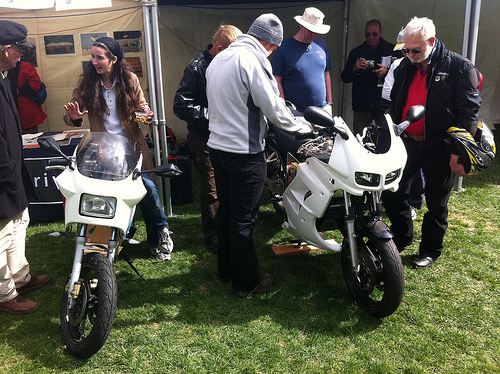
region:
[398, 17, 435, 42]
short cut white hair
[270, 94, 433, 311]
part of a white motorcycle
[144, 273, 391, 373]
a section of green grass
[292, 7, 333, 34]
a large white hat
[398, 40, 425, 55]
dark black sunglasses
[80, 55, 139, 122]
a woman's long brown hair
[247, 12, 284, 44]
a gray cap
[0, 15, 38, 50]
part of a man's black cap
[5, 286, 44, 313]
a man's brown shoe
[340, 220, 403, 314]
the wheel of a motorcycle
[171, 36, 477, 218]
people looking at a motorcycle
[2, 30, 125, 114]
a girl talking to a guy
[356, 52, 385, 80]
a guy holding a camera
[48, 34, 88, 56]
pictures hanging in a tent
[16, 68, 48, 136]
a person standing in a tent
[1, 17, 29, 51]
a guy wearing a black hat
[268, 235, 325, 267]
a block of wood supporting a foot on a motorcycle.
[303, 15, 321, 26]
man wearing white hat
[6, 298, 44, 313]
man wearing red shoes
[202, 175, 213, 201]
man wearing brown pants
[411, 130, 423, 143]
man wearing orange belt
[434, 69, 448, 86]
lettering on black coat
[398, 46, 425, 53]
man wearing black shades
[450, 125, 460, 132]
yellow on mans helmet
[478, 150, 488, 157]
grey on man's helmet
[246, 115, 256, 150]
blue stripe on jacket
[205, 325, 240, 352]
green grass in field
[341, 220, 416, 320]
front wheel on bike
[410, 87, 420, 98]
man wearing red shirt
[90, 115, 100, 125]
woman wearing brown coat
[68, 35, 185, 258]
Woman sitting on a motorcycle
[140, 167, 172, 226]
woman wearing blue jeans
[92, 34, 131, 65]
woman wearing a black scarf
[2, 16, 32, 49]
man wearing a black hat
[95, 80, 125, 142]
woman wearing a white shirt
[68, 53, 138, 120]
woman with long brown hair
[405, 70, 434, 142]
man wearing a red shirt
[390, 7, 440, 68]
man with gray hair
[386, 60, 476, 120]
man wearing a black jacket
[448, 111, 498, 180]
man wearing a helmet